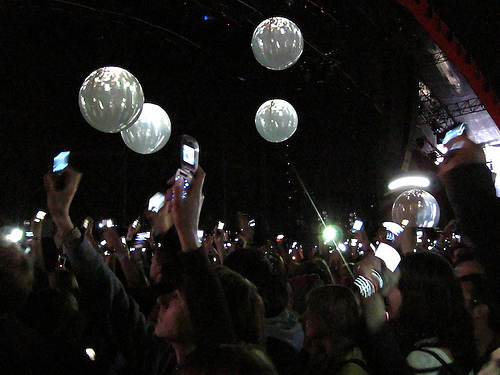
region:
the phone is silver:
[137, 123, 227, 229]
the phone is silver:
[126, 138, 247, 274]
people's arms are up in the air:
[33, 110, 280, 367]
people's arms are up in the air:
[240, 181, 418, 366]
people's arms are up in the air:
[341, 158, 443, 303]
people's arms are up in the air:
[66, 148, 233, 297]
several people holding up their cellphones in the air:
[0, 120, 495, 367]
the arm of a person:
[31, 150, 147, 355]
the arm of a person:
[165, 165, 232, 342]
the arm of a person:
[436, 131, 497, 237]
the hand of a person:
[208, 226, 225, 260]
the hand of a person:
[235, 208, 259, 246]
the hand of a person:
[102, 215, 122, 251]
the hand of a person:
[121, 215, 142, 237]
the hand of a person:
[78, 213, 98, 238]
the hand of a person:
[28, 208, 52, 238]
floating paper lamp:
[65, 62, 143, 133]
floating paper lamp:
[117, 103, 168, 157]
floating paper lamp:
[251, 109, 295, 143]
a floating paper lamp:
[252, 21, 302, 63]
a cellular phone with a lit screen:
[44, 146, 89, 193]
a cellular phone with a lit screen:
[174, 138, 216, 209]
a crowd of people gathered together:
[14, 141, 498, 363]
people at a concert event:
[14, 132, 498, 372]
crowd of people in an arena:
[11, 166, 498, 364]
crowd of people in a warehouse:
[5, 205, 497, 367]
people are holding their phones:
[131, 115, 269, 346]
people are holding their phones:
[30, 125, 233, 346]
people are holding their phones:
[338, 158, 451, 345]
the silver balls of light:
[68, 60, 162, 164]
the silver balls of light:
[222, 8, 311, 195]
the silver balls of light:
[304, 168, 436, 252]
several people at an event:
[6, 138, 497, 373]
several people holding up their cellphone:
[2, 104, 499, 374]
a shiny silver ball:
[243, 16, 303, 71]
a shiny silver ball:
[249, 91, 303, 143]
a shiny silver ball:
[386, 188, 439, 226]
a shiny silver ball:
[68, 69, 143, 134]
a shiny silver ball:
[119, 98, 174, 157]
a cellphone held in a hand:
[164, 129, 210, 220]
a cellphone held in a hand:
[36, 141, 82, 212]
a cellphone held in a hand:
[98, 217, 123, 249]